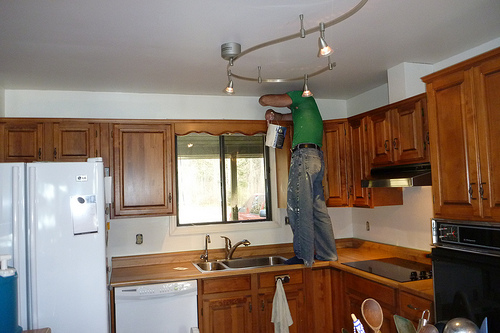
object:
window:
[169, 127, 285, 223]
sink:
[181, 237, 291, 283]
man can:
[256, 90, 339, 264]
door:
[114, 285, 200, 331]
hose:
[197, 232, 221, 270]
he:
[286, 80, 342, 272]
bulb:
[299, 90, 314, 98]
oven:
[428, 215, 500, 329]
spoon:
[358, 296, 385, 331]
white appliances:
[0, 156, 201, 333]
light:
[315, 34, 333, 63]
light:
[223, 73, 235, 97]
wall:
[346, 32, 496, 330]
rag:
[271, 278, 293, 331]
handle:
[269, 271, 289, 283]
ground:
[308, 65, 340, 117]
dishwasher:
[113, 281, 194, 333]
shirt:
[286, 88, 324, 147]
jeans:
[286, 144, 338, 264]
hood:
[360, 167, 432, 190]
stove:
[340, 254, 430, 284]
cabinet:
[113, 117, 174, 221]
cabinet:
[196, 266, 344, 332]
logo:
[75, 173, 87, 180]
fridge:
[2, 160, 107, 331]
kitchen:
[0, 0, 497, 333]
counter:
[113, 230, 430, 316]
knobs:
[466, 180, 486, 198]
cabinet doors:
[419, 48, 498, 225]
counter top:
[108, 236, 436, 300]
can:
[264, 120, 285, 150]